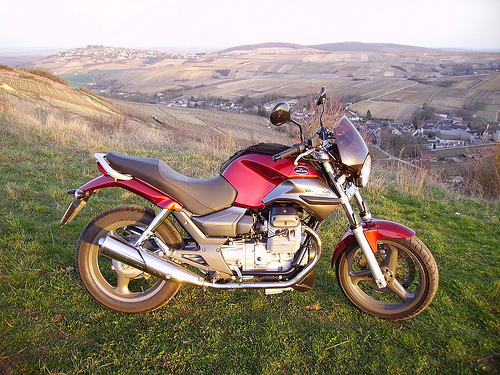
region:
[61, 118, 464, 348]
this is a bike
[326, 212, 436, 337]
the wheel of a bike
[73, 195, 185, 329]
the wheel of a bike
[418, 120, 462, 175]
this is a house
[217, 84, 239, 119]
this is a house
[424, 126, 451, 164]
this is a house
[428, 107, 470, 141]
this is a house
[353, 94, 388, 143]
this is a house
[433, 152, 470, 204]
this is a house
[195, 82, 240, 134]
this is a house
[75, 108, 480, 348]
A motorcycle on the hill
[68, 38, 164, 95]
A village in the background.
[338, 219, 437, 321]
A front tire of a bike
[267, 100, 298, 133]
Mirrors on a motorcycle.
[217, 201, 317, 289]
The engine of a motorcycle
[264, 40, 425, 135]
Farm land in the background.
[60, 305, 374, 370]
Green grass beside the bike.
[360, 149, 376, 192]
A light on a motorcycle.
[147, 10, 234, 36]
Cloudy skies over the village.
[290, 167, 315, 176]
Logo on the motorcycle.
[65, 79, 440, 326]
a motorcycle on the grass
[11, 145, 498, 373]
the grass is green and sunlit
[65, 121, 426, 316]
the motorcycle is red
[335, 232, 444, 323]
the tire is grey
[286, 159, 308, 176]
a label on the motorcycle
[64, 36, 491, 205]
a view of the countryside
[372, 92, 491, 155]
buildings in the valley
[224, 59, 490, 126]
fields in the mountainside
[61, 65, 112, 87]
this field is green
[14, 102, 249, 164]
brown grass on the hill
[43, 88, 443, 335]
the bike is red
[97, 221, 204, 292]
the muffler is chrome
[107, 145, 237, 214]
the seat is black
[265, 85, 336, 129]
the mirrors are black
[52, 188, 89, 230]
the motorcycle has a plate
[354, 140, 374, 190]
the bike has a light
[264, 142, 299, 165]
the handle has a grip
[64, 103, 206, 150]
the grass is long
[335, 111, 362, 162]
the visor is small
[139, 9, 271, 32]
the sky is white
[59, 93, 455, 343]
motorcycle on a mountain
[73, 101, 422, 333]
bike is red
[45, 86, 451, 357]
bike is black and shiny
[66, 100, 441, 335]
bike has two wheels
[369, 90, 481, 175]
buildings in valley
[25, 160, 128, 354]
grass is cut short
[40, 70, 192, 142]
grass is turning brown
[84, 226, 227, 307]
bike has exhaust pipe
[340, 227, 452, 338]
wheels have three spokes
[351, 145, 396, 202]
bike has headlight and farrings